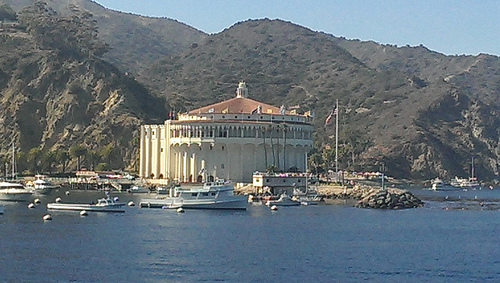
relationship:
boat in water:
[139, 183, 248, 210] [5, 182, 492, 280]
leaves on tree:
[41, 145, 61, 165] [46, 148, 86, 185]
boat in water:
[42, 198, 128, 212] [228, 210, 324, 265]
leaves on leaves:
[68, 142, 89, 157] [68, 142, 89, 157]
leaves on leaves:
[23, 144, 40, 167] [23, 148, 40, 164]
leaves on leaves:
[41, 149, 61, 164] [41, 149, 61, 164]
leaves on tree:
[51, 146, 73, 166] [84, 148, 99, 171]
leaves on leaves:
[68, 142, 89, 166] [104, 144, 121, 161]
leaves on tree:
[101, 140, 121, 162] [299, 148, 323, 176]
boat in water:
[265, 195, 300, 207] [5, 182, 492, 280]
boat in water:
[46, 202, 128, 213] [5, 182, 492, 280]